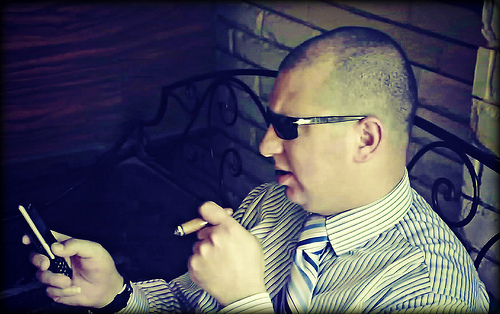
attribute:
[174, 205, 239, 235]
cigar — lit